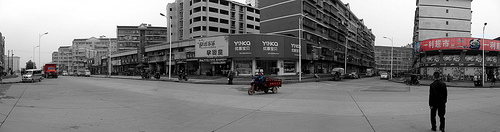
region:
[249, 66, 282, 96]
A man driving on the street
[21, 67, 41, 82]
A white van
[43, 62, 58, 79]
A large red truck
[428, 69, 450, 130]
A man in a black jacket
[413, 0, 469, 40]
A very large building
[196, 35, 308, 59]
An advertisement sign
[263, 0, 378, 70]
A very large building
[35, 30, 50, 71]
A tall street light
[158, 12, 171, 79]
A tall street light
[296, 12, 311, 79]
A tall street light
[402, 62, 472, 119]
a man is standing on the street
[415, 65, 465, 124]
the man is in all black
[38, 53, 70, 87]
a red truck down the street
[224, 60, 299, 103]
man driving a cart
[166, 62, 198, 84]
bike parked on the sidewalk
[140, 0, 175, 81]
the street light is off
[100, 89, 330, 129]
the street is grey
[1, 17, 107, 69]
the sky is overcast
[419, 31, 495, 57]
the top of the building is red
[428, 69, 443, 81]
the man`s hair is dark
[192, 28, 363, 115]
vehicle sitting in front of building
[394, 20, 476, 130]
man in front of store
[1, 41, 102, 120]
two vehicles in street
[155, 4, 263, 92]
view of high rise building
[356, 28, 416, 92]
street lamp in front of building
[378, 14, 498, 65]
red awning on building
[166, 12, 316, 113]
front of store building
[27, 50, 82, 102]
red dump truck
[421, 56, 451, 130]
lone man in black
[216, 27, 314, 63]
store with Asian writing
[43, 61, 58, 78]
A large, red truck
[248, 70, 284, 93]
A person driving on the road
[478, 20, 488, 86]
A tall street light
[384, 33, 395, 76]
A tall street light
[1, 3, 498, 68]
A cloudy, grey sky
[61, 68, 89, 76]
A line of parked cars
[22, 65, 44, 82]
A metallic grey automobile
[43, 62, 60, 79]
A big red truck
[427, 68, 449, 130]
A lone person walking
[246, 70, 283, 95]
A rider in a blue jacket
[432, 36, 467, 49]
A building with a red color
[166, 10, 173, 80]
A metallic lamp post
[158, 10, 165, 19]
The light suspended on a pole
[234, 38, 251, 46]
White writing on the wall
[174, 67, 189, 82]
Motorbike parked on the roadside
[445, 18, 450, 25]
A window on a building